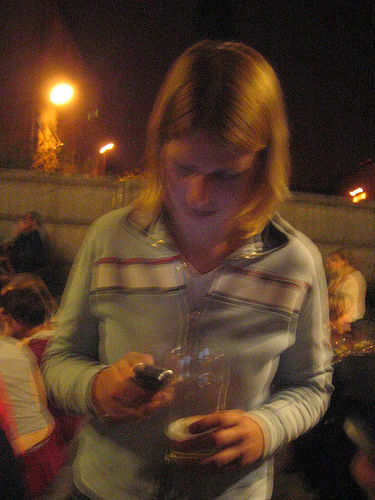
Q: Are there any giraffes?
A: No, there are no giraffes.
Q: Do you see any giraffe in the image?
A: No, there are no giraffes.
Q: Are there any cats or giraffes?
A: No, there are no giraffes or cats.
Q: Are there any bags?
A: No, there are no bags.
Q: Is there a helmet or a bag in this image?
A: No, there are no bags or helmets.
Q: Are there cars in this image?
A: No, there are no cars.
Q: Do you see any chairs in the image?
A: No, there are no chairs.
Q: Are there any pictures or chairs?
A: No, there are no chairs or pictures.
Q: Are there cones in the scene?
A: No, there are no cones.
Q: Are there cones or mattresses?
A: No, there are no cones or mattresses.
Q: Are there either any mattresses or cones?
A: No, there are no cones or mattresses.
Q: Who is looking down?
A: The girl is looking down.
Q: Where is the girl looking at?
A: The girl is looking down.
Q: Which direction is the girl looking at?
A: The girl is looking down.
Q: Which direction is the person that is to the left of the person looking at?
A: The girl is looking down.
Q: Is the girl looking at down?
A: Yes, the girl is looking down.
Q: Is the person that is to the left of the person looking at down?
A: Yes, the girl is looking down.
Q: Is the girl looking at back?
A: No, the girl is looking down.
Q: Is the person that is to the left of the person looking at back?
A: No, the girl is looking down.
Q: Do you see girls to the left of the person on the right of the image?
A: Yes, there is a girl to the left of the person.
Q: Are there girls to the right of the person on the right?
A: No, the girl is to the left of the person.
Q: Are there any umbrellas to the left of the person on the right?
A: No, there is a girl to the left of the person.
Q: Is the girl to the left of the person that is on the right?
A: Yes, the girl is to the left of the person.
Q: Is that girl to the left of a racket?
A: No, the girl is to the left of the person.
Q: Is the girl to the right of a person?
A: No, the girl is to the left of a person.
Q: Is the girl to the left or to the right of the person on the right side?
A: The girl is to the left of the person.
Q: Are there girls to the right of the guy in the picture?
A: Yes, there is a girl to the right of the guy.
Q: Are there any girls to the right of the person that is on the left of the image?
A: Yes, there is a girl to the right of the guy.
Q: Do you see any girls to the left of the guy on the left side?
A: No, the girl is to the right of the guy.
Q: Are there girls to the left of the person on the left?
A: No, the girl is to the right of the guy.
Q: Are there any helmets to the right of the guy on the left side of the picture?
A: No, there is a girl to the right of the guy.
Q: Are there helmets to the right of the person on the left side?
A: No, there is a girl to the right of the guy.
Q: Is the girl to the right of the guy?
A: Yes, the girl is to the right of the guy.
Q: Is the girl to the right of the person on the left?
A: Yes, the girl is to the right of the guy.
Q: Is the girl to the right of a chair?
A: No, the girl is to the right of the guy.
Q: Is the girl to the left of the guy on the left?
A: No, the girl is to the right of the guy.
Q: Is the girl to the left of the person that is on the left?
A: No, the girl is to the right of the guy.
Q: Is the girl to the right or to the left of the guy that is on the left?
A: The girl is to the right of the guy.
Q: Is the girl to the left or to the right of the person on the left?
A: The girl is to the right of the guy.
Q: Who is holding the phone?
A: The girl is holding the phone.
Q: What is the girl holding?
A: The girl is holding the telephone.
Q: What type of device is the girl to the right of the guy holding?
A: The girl is holding the telephone.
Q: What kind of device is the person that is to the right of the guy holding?
A: The girl is holding the telephone.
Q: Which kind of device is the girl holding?
A: The girl is holding the telephone.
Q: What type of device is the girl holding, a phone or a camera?
A: The girl is holding a phone.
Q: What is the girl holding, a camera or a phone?
A: The girl is holding a phone.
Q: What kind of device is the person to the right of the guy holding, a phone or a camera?
A: The girl is holding a phone.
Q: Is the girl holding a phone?
A: Yes, the girl is holding a phone.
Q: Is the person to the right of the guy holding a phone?
A: Yes, the girl is holding a phone.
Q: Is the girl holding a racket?
A: No, the girl is holding a phone.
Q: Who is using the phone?
A: The girl is using the phone.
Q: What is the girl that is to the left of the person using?
A: The girl is using a phone.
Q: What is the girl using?
A: The girl is using a phone.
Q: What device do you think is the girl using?
A: The girl is using a telephone.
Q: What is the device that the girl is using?
A: The device is a phone.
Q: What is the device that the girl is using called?
A: The device is a phone.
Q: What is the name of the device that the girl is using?
A: The device is a phone.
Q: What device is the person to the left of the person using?
A: The girl is using a telephone.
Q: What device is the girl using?
A: The girl is using a telephone.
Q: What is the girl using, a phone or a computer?
A: The girl is using a phone.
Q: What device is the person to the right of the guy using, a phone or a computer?
A: The girl is using a phone.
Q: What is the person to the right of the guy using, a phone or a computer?
A: The girl is using a phone.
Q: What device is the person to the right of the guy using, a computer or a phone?
A: The girl is using a phone.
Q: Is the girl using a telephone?
A: Yes, the girl is using a telephone.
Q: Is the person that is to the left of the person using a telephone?
A: Yes, the girl is using a telephone.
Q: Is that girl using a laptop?
A: No, the girl is using a telephone.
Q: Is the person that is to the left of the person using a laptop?
A: No, the girl is using a telephone.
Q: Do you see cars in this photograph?
A: No, there are no cars.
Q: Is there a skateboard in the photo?
A: No, there are no skateboards.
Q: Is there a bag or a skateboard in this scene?
A: No, there are no skateboards or bags.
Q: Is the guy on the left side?
A: Yes, the guy is on the left of the image.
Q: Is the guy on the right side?
A: No, the guy is on the left of the image.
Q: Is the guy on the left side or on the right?
A: The guy is on the left of the image.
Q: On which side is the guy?
A: The guy is on the left of the image.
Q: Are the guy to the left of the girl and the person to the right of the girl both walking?
A: Yes, both the guy and the person are walking.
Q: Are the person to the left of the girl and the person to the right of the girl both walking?
A: Yes, both the guy and the person are walking.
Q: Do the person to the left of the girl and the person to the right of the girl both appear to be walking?
A: Yes, both the guy and the person are walking.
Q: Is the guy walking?
A: Yes, the guy is walking.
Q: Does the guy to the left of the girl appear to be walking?
A: Yes, the guy is walking.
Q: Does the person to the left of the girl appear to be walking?
A: Yes, the guy is walking.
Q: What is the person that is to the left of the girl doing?
A: The guy is walking.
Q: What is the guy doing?
A: The guy is walking.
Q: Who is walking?
A: The guy is walking.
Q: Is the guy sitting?
A: No, the guy is walking.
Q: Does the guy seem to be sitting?
A: No, the guy is walking.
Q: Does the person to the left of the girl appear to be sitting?
A: No, the guy is walking.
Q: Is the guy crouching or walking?
A: The guy is walking.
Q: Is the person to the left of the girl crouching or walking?
A: The guy is walking.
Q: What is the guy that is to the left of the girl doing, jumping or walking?
A: The guy is walking.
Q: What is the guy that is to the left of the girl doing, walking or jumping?
A: The guy is walking.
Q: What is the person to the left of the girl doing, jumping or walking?
A: The guy is walking.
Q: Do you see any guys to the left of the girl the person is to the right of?
A: Yes, there is a guy to the left of the girl.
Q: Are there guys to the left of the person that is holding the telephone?
A: Yes, there is a guy to the left of the girl.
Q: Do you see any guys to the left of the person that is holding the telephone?
A: Yes, there is a guy to the left of the girl.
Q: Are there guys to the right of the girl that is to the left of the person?
A: No, the guy is to the left of the girl.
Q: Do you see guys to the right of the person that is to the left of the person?
A: No, the guy is to the left of the girl.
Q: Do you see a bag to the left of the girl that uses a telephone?
A: No, there is a guy to the left of the girl.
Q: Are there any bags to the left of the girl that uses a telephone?
A: No, there is a guy to the left of the girl.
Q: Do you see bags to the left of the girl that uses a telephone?
A: No, there is a guy to the left of the girl.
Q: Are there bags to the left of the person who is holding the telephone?
A: No, there is a guy to the left of the girl.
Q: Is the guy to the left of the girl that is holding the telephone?
A: Yes, the guy is to the left of the girl.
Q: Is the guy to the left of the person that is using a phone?
A: Yes, the guy is to the left of the girl.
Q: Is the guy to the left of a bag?
A: No, the guy is to the left of the girl.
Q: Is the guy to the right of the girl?
A: No, the guy is to the left of the girl.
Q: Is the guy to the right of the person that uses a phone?
A: No, the guy is to the left of the girl.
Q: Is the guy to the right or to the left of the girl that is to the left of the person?
A: The guy is to the left of the girl.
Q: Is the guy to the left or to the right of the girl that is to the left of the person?
A: The guy is to the left of the girl.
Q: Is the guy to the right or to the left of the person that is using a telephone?
A: The guy is to the left of the girl.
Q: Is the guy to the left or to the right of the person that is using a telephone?
A: The guy is to the left of the girl.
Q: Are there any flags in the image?
A: No, there are no flags.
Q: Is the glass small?
A: Yes, the glass is small.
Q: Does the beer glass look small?
A: Yes, the glass is small.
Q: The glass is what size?
A: The glass is small.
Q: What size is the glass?
A: The glass is small.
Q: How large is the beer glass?
A: The glass is small.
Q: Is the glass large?
A: No, the glass is small.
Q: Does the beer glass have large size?
A: No, the glass is small.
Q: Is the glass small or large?
A: The glass is small.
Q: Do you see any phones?
A: Yes, there is a phone.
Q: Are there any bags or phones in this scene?
A: Yes, there is a phone.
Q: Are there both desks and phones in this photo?
A: No, there is a phone but no desks.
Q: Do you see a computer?
A: No, there are no computers.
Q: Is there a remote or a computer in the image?
A: No, there are no computers or remote controls.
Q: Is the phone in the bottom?
A: Yes, the phone is in the bottom of the image.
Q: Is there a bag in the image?
A: No, there are no bags.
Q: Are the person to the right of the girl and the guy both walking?
A: Yes, both the person and the guy are walking.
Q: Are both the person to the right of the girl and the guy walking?
A: Yes, both the person and the guy are walking.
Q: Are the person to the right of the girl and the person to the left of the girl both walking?
A: Yes, both the person and the guy are walking.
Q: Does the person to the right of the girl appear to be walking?
A: Yes, the person is walking.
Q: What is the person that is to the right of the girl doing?
A: The person is walking.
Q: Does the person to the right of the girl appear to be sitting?
A: No, the person is walking.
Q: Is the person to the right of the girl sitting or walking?
A: The person is walking.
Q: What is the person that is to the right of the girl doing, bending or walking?
A: The person is walking.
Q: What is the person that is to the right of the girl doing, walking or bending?
A: The person is walking.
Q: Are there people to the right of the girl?
A: Yes, there is a person to the right of the girl.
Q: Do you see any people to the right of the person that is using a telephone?
A: Yes, there is a person to the right of the girl.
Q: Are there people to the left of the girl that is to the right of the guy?
A: No, the person is to the right of the girl.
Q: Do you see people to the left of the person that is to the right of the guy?
A: No, the person is to the right of the girl.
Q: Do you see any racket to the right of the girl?
A: No, there is a person to the right of the girl.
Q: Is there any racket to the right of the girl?
A: No, there is a person to the right of the girl.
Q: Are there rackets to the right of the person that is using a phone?
A: No, there is a person to the right of the girl.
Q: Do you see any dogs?
A: No, there are no dogs.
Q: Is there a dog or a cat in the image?
A: No, there are no dogs or cats.